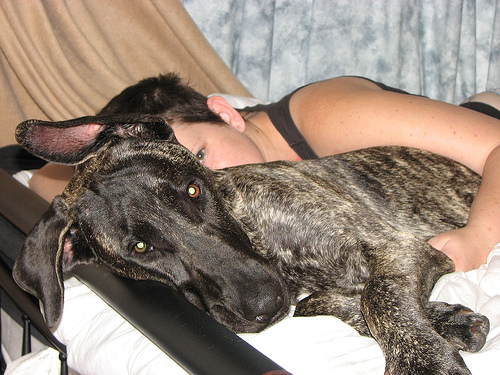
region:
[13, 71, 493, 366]
a dog laying next to a person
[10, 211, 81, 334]
the ear of a dog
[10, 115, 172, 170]
the ear of a dog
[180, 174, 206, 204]
the eye of a dog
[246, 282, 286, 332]
the nose of a dog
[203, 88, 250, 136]
the ear of a person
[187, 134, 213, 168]
the eye of a person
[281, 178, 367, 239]
the fur of a dog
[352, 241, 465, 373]
the leg of a dog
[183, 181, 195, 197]
one of eyes on the dog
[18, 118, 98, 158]
one of the ears on the dog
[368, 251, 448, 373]
one of the legs on dog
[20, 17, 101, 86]
a portion of brown curtain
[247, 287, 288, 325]
the nose on the dog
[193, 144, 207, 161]
the eye on the boy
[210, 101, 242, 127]
the ear on the boy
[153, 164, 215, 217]
eye of the dog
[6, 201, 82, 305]
ear of the dog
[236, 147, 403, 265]
brown and black dog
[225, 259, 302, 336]
nose of the dog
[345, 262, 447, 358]
paw of the dog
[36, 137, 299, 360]
head of the dog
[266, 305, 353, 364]
white sheet under dog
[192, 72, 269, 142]
ear of the kid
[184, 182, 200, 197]
the left brown eye of a dog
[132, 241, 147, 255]
the right brown eye of a dog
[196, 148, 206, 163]
the right green eye of a woman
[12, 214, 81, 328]
the floppy right ear of a dog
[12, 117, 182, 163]
the flipped back left ear of a dog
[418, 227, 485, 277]
a woman's hand under the dog's elbow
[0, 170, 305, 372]
the metal frame of a bed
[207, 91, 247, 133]
a woman's right ear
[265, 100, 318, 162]
the strap of a black tank top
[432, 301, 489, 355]
the right paw of a dog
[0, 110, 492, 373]
Dog on the bed.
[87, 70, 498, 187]
Person laying on the bed.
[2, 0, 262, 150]
Brown drapes in the background.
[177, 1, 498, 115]
Marbled drapes in the background.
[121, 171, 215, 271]
Brown eyes on the dog.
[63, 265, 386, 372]
White pillow on the bed.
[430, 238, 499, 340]
White blanket on the bed.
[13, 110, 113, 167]
Pink color inside dog's ear.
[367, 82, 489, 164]
Freckles on the arm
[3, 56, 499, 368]
person laying with a dog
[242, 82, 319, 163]
a black strap shirt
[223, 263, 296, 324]
nose on the dog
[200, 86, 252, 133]
ear of the person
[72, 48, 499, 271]
person holding the dog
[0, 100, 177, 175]
the dog ear is flipped over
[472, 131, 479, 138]
freckle on woman's arm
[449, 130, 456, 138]
freckle on woman's arm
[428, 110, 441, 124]
freckle on woman's arm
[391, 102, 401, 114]
freckle on woman's arm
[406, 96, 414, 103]
freckle on woman's arm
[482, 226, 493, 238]
freckle on woman's arm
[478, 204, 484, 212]
freckle on woman's arm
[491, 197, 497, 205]
freckle on woman's arm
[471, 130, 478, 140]
freckle on woman's arm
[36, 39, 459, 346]
a scene of a person a dog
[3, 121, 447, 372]
a white and black bed